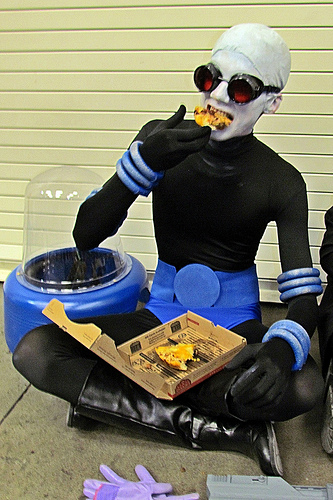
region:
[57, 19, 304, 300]
person eating piece of pizza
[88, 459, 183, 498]
purple gloves on the ground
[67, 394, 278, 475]
black boots on feet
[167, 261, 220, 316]
blue circle on front of stomach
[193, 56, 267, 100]
red and black goggles onf ace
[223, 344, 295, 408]
black gloves on hand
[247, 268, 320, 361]
faded blue rings on arm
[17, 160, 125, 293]
plastic helmet on the ground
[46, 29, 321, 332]
person dressed up as mr. freeze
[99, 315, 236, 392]
brown card board box of food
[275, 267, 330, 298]
3 blue bracelets on arm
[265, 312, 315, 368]
2 blue bracelets on wrist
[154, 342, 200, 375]
cheese pizza in box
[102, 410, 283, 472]
tall black boot on person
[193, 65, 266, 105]
black goggles on face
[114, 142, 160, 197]
set of 3 bracelets on wrist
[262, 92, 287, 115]
the person's left ear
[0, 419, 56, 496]
cement pavement on ground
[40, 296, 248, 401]
small brown pizza box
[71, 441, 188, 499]
the gloves on the ground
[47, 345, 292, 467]
the boots are black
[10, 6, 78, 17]
White lone on door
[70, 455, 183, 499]
Purple gloves on ground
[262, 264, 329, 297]
Blue bracelets on arm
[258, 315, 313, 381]
Blue bracelets on arm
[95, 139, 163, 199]
Blue bracelets on arm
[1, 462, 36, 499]
Small patch of concrete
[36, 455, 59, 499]
Small patch of concrete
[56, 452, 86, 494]
Small patch of concrete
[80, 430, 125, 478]
Small patch of concrete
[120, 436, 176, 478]
Small patch of concrete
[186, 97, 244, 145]
a person from the future eating food.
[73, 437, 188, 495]
a pair of purple gloves.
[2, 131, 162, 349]
a clear case next to a girl.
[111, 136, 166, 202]
blue bracelets on a girl.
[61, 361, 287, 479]
a long shiny black boot.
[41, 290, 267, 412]
a brown pizza box.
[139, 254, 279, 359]
a pair of blue shorts.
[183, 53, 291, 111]
a air of dark goggles.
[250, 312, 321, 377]
blue rings on an arm.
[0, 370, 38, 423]
a line in a sidewalk.